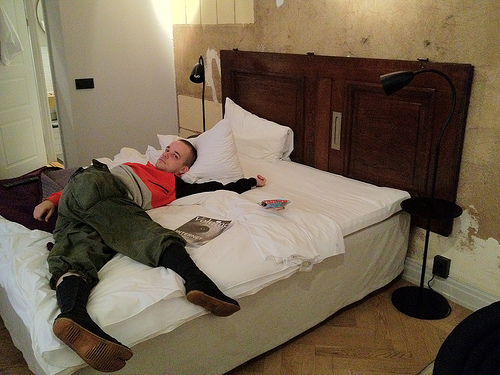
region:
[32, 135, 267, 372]
man draped across bed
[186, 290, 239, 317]
sole of man's left shoe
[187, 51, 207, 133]
black lamp next to bed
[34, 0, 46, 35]
portion of oval bathroom mirror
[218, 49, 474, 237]
dark brown wooden headboard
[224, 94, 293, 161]
bed pillow with white cover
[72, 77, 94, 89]
black light switch on wall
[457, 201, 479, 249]
section of chipped paint on wall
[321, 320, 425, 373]
wooden parquet style floor section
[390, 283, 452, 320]
round base of black lamp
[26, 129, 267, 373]
A man sprawled out.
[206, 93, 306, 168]
a large white pillow.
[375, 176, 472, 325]
a small black table.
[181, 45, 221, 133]
a lamp near a bed.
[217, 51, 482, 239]
a large wooden headboard.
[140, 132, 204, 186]
A man with short hair.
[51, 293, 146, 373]
a right foot boot.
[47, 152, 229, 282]
A pair of green pants.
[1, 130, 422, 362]
a pad on a mattress.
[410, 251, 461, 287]
a plug in a wall.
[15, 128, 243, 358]
person laying on bed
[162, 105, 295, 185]
two white pillows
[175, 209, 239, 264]
magazine on top of bed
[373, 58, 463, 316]
black bedside floor lamp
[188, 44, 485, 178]
large wooden head baord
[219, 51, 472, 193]
head board made from an old door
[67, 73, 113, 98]
black light switch on walls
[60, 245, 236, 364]
man wearing black boots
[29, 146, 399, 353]
bed with white sheets and comforter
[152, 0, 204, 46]
sunlight shining on wall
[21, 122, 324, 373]
guy laying twisted on bed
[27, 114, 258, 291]
guy wearing short green pants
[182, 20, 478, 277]
brown headboard against the wall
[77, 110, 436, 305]
white sheets on bed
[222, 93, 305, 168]
white pillowcase on pillow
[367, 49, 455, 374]
black floor lamp on floor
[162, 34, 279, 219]
black lamp next to bed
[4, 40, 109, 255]
open door to bedroom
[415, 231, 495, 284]
black electric outlet on white wall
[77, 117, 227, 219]
guy wearing red and black shirt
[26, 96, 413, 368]
Man lying awkwardly on bed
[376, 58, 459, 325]
Black floor lamp next to bed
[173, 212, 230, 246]
Magazine on bed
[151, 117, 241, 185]
Man's head on pillow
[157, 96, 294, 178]
Two pillows on the bed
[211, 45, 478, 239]
Brown wooden headboard on wall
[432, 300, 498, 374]
Round table in corner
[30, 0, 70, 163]
Open doorway to another room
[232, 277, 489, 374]
Wooden floor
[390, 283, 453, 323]
Base of floorlamp